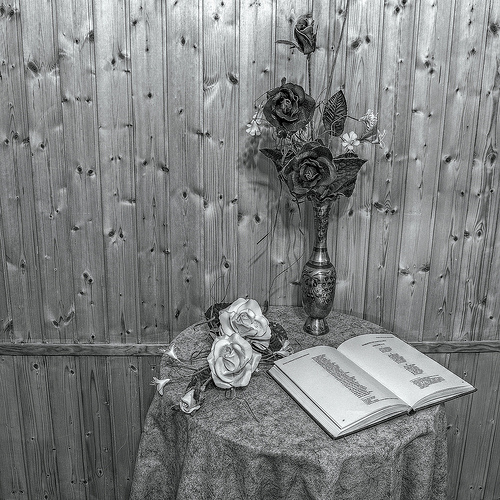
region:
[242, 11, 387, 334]
Flowers in a decorative vase.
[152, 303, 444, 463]
A round table.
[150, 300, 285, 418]
Flowers on top of the table.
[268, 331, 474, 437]
An open book on the table.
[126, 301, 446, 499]
A tablecloth draped over the table.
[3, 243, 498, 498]
A wooden wall behind the table.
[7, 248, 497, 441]
knots in the wood on the wall.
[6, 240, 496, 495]
A wood panel wall.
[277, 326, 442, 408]
Words on the center of the pages.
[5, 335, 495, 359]
A wooden strip along the wooden wall.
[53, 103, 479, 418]
a black and white photo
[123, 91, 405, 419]
flowers on a table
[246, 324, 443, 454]
a book on the table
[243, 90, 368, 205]
these flowes are dark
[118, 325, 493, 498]
a table cloth on the table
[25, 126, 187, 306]
a woodn wall with cracks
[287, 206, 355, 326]
a vase on the table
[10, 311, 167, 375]
a wooden line in the wall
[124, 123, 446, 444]
this is some type of display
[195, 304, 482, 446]
words on a page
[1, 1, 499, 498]
another hdr photograph, i think, this time in black+white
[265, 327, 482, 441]
book on table, looks not quite like illustration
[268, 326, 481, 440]
book is poetry book of some sort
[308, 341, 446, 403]
words are illegible, even the language is uncertain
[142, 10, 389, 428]
roses appear to be silk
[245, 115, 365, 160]
little white fabric flowers amid the dark roses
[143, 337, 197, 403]
little white lilylike flowers amid the light roses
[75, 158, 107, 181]
tiny holes in the wall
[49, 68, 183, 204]
shine on the wall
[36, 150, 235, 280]
silver color on the surface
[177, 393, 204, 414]
small rose petal on table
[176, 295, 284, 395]
small bouquet of roses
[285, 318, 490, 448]
book on table top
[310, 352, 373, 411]
words on the open book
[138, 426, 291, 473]
decorative table cloth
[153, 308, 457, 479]
small round table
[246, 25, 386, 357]
bouquet of flowers in decorative vase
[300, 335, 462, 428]
the book is open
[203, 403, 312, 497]
the table clothe is grey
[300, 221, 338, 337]
the vase is made of glasss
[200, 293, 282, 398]
the flowers are artifial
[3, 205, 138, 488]
the fence is wooden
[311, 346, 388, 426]
the letters are in a column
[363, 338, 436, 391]
the letters are in a column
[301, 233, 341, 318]
the vase is decorated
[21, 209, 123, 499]
the fence is grey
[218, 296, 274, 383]
the flowers are white in color